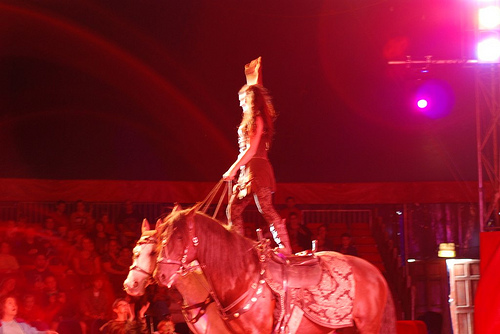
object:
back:
[260, 251, 352, 274]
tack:
[155, 233, 356, 334]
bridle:
[123, 218, 164, 297]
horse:
[153, 202, 395, 334]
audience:
[0, 197, 359, 334]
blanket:
[265, 251, 355, 329]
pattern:
[291, 251, 356, 329]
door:
[445, 258, 480, 334]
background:
[389, 209, 498, 333]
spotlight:
[410, 79, 455, 119]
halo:
[408, 81, 455, 119]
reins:
[197, 178, 233, 219]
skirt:
[232, 157, 277, 200]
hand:
[245, 56, 263, 85]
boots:
[269, 218, 291, 256]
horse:
[123, 218, 233, 334]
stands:
[0, 194, 358, 334]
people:
[0, 196, 357, 334]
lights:
[475, 0, 500, 66]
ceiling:
[0, 0, 500, 182]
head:
[238, 84, 265, 113]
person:
[223, 84, 292, 258]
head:
[90, 277, 104, 288]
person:
[78, 278, 107, 332]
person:
[100, 297, 137, 334]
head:
[112, 298, 130, 314]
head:
[0, 293, 19, 317]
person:
[0, 294, 38, 334]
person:
[43, 274, 66, 312]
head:
[39, 272, 58, 295]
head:
[75, 200, 86, 211]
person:
[91, 221, 112, 256]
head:
[94, 221, 105, 231]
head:
[122, 200, 134, 214]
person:
[116, 199, 142, 231]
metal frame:
[471, 63, 484, 233]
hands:
[222, 170, 237, 181]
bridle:
[153, 202, 205, 287]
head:
[153, 201, 206, 287]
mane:
[193, 211, 259, 294]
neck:
[196, 211, 247, 303]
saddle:
[256, 227, 324, 288]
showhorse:
[122, 202, 396, 334]